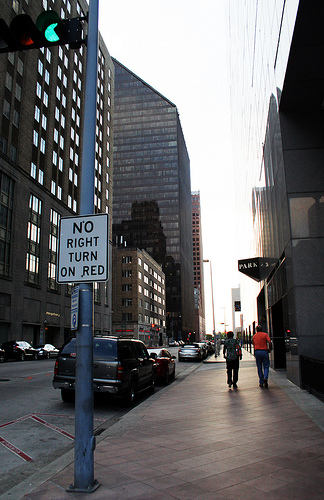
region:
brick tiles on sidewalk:
[164, 436, 246, 470]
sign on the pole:
[60, 220, 103, 282]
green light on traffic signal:
[39, 13, 67, 38]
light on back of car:
[110, 360, 125, 379]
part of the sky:
[135, 11, 212, 62]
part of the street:
[9, 385, 51, 406]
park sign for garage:
[234, 259, 271, 271]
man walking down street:
[249, 323, 272, 390]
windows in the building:
[45, 91, 69, 134]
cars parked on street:
[9, 341, 53, 354]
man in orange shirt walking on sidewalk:
[248, 324, 276, 390]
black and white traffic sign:
[60, 217, 109, 281]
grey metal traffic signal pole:
[71, 357, 99, 490]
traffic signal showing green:
[0, 12, 89, 50]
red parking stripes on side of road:
[1, 409, 75, 471]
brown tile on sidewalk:
[168, 409, 257, 483]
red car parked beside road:
[147, 341, 184, 389]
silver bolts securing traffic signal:
[72, 12, 81, 49]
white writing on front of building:
[230, 256, 267, 275]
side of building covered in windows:
[33, 85, 79, 186]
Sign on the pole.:
[59, 194, 147, 302]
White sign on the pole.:
[48, 191, 123, 290]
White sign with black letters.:
[54, 210, 116, 301]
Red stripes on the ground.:
[32, 401, 91, 466]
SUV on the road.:
[42, 317, 158, 406]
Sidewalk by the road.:
[142, 381, 241, 467]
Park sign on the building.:
[229, 244, 291, 282]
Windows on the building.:
[128, 245, 173, 321]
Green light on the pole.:
[32, 12, 94, 43]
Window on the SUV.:
[104, 327, 159, 397]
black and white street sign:
[50, 211, 123, 292]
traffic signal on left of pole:
[5, 9, 83, 54]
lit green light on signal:
[37, 9, 68, 49]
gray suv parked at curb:
[48, 327, 163, 408]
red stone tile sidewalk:
[144, 414, 231, 499]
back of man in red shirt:
[246, 324, 281, 392]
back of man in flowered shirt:
[218, 329, 242, 393]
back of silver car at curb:
[176, 342, 201, 368]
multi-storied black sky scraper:
[111, 55, 211, 340]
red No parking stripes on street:
[5, 405, 98, 476]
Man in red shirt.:
[245, 313, 276, 384]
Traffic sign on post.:
[49, 198, 108, 290]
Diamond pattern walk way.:
[175, 418, 231, 481]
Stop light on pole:
[4, 7, 73, 49]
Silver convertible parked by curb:
[168, 334, 205, 365]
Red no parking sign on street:
[7, 405, 60, 470]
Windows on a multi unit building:
[140, 271, 165, 320]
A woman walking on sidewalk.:
[219, 325, 255, 398]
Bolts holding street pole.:
[52, 466, 112, 496]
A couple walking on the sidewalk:
[219, 325, 282, 391]